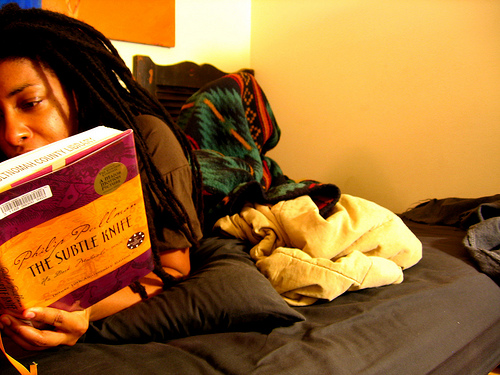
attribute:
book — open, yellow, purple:
[0, 111, 162, 346]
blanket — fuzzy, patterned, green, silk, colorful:
[176, 62, 345, 219]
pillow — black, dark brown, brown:
[51, 226, 310, 355]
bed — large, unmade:
[0, 245, 497, 374]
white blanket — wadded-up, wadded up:
[206, 187, 428, 312]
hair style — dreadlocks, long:
[1, 2, 208, 303]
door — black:
[124, 44, 258, 105]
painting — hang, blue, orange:
[21, 0, 190, 57]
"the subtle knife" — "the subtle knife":
[22, 211, 141, 282]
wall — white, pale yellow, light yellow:
[261, 8, 494, 197]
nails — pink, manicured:
[1, 297, 39, 339]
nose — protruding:
[1, 106, 36, 150]